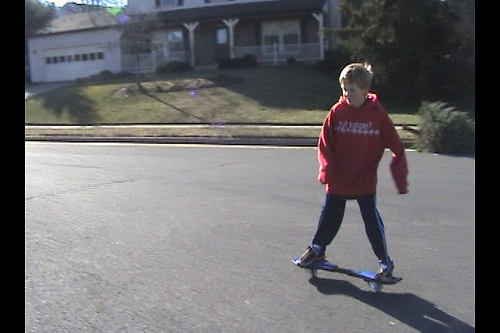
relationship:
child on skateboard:
[297, 61, 409, 279] [313, 258, 403, 291]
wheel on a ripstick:
[365, 279, 386, 294] [288, 254, 404, 296]